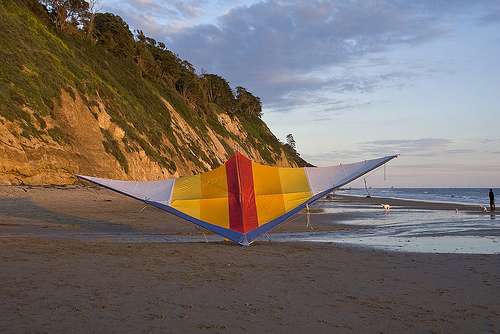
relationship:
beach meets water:
[0, 190, 499, 333] [333, 186, 500, 207]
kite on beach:
[74, 148, 399, 246] [0, 190, 499, 333]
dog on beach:
[379, 202, 392, 214] [0, 190, 499, 333]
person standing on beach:
[488, 186, 496, 215] [0, 190, 499, 333]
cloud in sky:
[163, 0, 493, 114] [62, 0, 499, 188]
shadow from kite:
[1, 194, 142, 242] [74, 148, 399, 246]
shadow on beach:
[1, 194, 142, 242] [0, 190, 499, 333]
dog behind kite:
[379, 202, 392, 214] [74, 148, 399, 246]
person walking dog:
[488, 186, 496, 215] [379, 202, 392, 214]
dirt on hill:
[1, 120, 294, 185] [0, 0, 317, 188]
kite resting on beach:
[74, 148, 399, 246] [0, 190, 499, 333]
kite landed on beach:
[74, 148, 399, 246] [0, 190, 499, 333]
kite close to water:
[74, 148, 399, 246] [333, 186, 500, 207]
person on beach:
[488, 186, 496, 215] [0, 190, 499, 333]